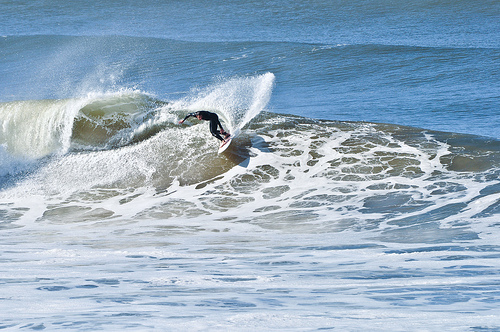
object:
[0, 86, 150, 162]
wave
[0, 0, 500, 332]
ocean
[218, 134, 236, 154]
surfboard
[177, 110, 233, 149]
man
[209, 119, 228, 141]
pants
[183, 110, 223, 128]
shirt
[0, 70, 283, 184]
waves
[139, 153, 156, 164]
caps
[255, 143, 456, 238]
foam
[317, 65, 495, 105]
ripple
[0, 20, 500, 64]
wave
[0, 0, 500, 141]
background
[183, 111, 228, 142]
suit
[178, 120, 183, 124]
hand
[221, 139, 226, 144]
feet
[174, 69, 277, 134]
water spray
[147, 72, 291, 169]
surface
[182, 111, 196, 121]
sleeves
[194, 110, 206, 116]
hair